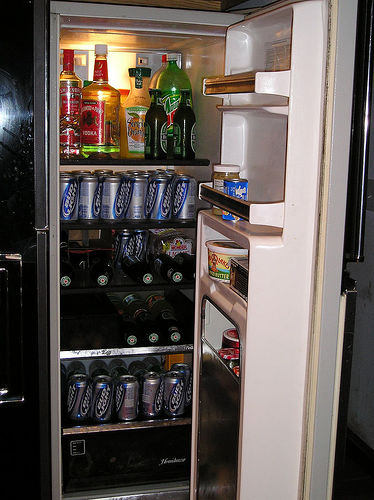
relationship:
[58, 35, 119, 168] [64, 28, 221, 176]
vodka bottles are on top shelf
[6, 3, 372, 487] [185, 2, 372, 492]
refrigerator has door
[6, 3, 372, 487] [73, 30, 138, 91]
refrigerator has light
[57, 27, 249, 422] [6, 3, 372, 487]
items are in refrigerator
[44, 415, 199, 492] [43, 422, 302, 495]
crisper drawer on bottom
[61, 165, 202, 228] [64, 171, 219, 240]
beer cans are on shelf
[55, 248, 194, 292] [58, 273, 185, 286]
beer bottles have green caps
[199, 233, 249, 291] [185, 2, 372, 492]
margarine tub in door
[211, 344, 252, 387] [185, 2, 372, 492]
jelly in door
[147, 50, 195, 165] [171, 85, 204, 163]
soda bottle behind bottle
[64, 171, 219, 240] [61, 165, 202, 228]
shelf has beer cans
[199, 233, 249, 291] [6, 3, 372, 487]
margarine tub in refrigerator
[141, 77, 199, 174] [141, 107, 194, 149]
two bottles of beer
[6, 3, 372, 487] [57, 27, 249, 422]
refrigerator full of items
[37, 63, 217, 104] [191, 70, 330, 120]
no bread in picture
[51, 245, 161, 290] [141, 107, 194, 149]
three bottles of beer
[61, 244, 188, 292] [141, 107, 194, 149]
four bottles of beer